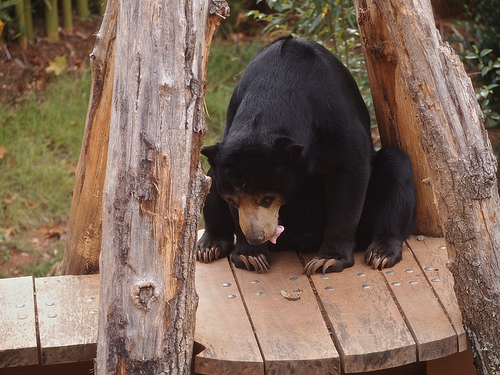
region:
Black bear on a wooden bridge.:
[198, 31, 413, 272]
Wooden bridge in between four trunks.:
[2, 234, 476, 371]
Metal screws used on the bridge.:
[13, 245, 449, 320]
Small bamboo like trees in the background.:
[3, 3, 100, 43]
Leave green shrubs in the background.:
[212, 3, 497, 138]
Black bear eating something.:
[241, 223, 291, 246]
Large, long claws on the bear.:
[196, 242, 403, 271]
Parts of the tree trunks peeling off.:
[138, 124, 187, 321]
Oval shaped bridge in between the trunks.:
[186, 215, 478, 374]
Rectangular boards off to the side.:
[6, 267, 108, 359]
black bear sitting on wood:
[202, 35, 414, 280]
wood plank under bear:
[309, 253, 386, 304]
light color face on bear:
[220, 185, 297, 259]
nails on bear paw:
[301, 254, 340, 279]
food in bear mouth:
[266, 219, 293, 253]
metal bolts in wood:
[370, 262, 434, 293]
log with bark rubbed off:
[131, 192, 195, 313]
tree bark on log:
[162, 295, 194, 364]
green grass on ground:
[21, 103, 76, 163]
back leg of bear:
[361, 146, 418, 276]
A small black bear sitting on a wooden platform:
[187, 27, 421, 276]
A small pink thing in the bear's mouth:
[255, 222, 289, 244]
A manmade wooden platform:
[0, 230, 474, 372]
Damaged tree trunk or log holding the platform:
[90, 2, 202, 369]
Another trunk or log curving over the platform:
[360, 5, 499, 371]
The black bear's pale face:
[216, 187, 285, 246]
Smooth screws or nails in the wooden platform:
[213, 255, 472, 304]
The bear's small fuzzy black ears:
[192, 129, 312, 167]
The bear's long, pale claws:
[189, 237, 400, 280]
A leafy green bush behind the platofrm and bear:
[243, 0, 498, 140]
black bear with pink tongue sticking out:
[208, 36, 412, 274]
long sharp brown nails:
[299, 255, 354, 275]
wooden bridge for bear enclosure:
[7, 7, 487, 364]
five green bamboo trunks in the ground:
[8, 4, 90, 44]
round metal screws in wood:
[220, 281, 235, 304]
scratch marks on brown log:
[140, 148, 182, 259]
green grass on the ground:
[3, 101, 60, 241]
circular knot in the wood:
[129, 279, 161, 311]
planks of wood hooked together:
[206, 277, 452, 369]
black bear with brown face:
[200, 141, 306, 246]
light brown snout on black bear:
[218, 190, 282, 245]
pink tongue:
[271, 222, 284, 245]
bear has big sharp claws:
[303, 256, 341, 276]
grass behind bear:
[0, 72, 82, 277]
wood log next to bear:
[93, 0, 207, 373]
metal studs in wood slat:
[221, 280, 231, 287]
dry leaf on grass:
[44, 51, 70, 76]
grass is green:
[206, 35, 254, 144]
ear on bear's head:
[280, 141, 304, 161]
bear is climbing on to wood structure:
[195, 35, 417, 277]